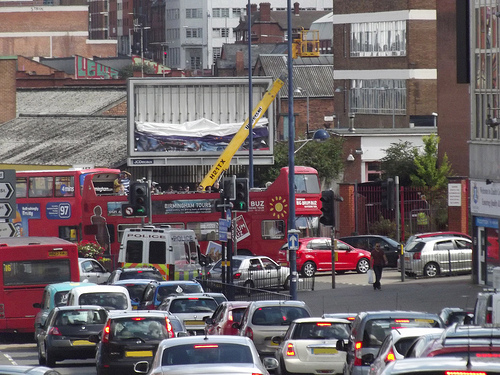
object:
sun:
[268, 196, 288, 215]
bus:
[131, 164, 323, 264]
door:
[146, 234, 164, 272]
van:
[113, 224, 202, 283]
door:
[123, 237, 145, 270]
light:
[102, 325, 112, 333]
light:
[165, 317, 171, 335]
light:
[132, 316, 144, 322]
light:
[286, 343, 294, 355]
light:
[314, 320, 332, 328]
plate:
[312, 349, 337, 355]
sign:
[215, 216, 230, 242]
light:
[134, 208, 147, 215]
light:
[235, 200, 248, 210]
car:
[279, 237, 373, 276]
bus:
[3, 164, 129, 259]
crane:
[195, 30, 320, 189]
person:
[367, 242, 389, 290]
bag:
[368, 270, 379, 284]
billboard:
[126, 75, 274, 166]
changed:
[132, 116, 271, 151]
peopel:
[61, 185, 73, 197]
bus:
[1, 234, 81, 336]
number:
[58, 205, 70, 217]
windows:
[388, 21, 409, 58]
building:
[330, 3, 467, 195]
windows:
[351, 79, 406, 112]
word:
[127, 233, 165, 238]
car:
[209, 254, 297, 292]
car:
[278, 315, 351, 373]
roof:
[1, 114, 127, 165]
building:
[1, 81, 130, 171]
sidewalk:
[298, 274, 484, 315]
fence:
[353, 181, 401, 233]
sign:
[447, 182, 462, 206]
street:
[289, 255, 472, 282]